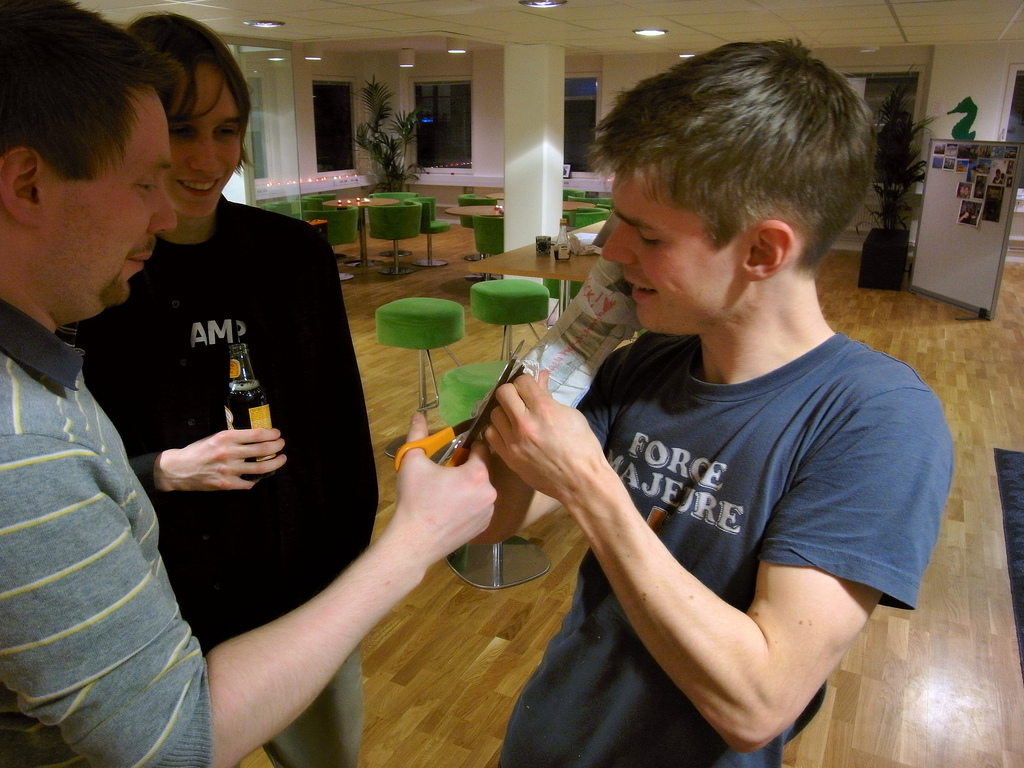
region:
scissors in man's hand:
[376, 334, 532, 508]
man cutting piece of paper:
[3, 2, 509, 767]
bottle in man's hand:
[213, 336, 287, 467]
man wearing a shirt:
[63, 192, 396, 657]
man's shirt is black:
[60, 194, 397, 663]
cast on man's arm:
[456, 252, 650, 496]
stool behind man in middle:
[355, 286, 473, 435]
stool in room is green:
[358, 284, 479, 436]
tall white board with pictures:
[901, 126, 1022, 341]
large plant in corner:
[346, 68, 430, 212]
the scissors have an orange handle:
[396, 339, 524, 469]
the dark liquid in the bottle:
[220, 338, 275, 479]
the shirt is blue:
[500, 331, 954, 766]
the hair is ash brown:
[586, 31, 880, 278]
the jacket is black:
[74, 203, 378, 660]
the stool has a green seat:
[374, 294, 467, 462]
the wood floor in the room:
[1, 2, 1022, 767]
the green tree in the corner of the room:
[0, 0, 1022, 765]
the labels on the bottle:
[220, 338, 277, 484]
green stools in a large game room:
[370, 290, 469, 415]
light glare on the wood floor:
[879, 601, 1022, 766]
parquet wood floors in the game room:
[355, 599, 559, 764]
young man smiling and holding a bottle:
[166, 14, 369, 562]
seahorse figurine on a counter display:
[906, 87, 1020, 321]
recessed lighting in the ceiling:
[248, 0, 692, 70]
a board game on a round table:
[318, 185, 402, 281]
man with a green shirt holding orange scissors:
[0, 334, 523, 762]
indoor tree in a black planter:
[861, 81, 919, 291]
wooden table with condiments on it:
[470, 205, 595, 282]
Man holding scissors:
[378, 329, 535, 470]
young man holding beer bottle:
[215, 339, 273, 467]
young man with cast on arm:
[552, 256, 604, 400]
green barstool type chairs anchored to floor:
[362, 188, 419, 274]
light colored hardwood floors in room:
[874, 615, 980, 752]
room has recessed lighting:
[617, 21, 668, 35]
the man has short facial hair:
[86, 232, 162, 312]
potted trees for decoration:
[358, 80, 419, 186]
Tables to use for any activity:
[317, 197, 406, 284]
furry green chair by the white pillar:
[427, 365, 539, 593]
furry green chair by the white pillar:
[371, 289, 467, 423]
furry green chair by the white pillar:
[463, 270, 544, 368]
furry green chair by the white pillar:
[362, 194, 419, 268]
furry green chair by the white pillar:
[296, 191, 358, 281]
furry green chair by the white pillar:
[418, 188, 447, 266]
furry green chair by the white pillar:
[468, 207, 506, 268]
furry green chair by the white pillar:
[447, 188, 493, 259]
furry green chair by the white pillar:
[563, 201, 602, 228]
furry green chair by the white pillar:
[539, 269, 579, 328]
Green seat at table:
[366, 291, 469, 358]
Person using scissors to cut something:
[372, 333, 546, 479]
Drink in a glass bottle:
[199, 326, 286, 438]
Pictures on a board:
[926, 133, 1012, 223]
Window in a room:
[405, 74, 473, 166]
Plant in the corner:
[332, 59, 430, 199]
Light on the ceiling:
[239, 8, 293, 46]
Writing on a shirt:
[597, 416, 757, 533]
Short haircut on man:
[594, 35, 855, 296]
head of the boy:
[522, 40, 916, 363]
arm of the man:
[518, 430, 841, 766]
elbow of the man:
[707, 629, 832, 766]